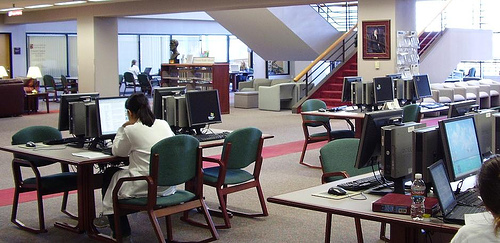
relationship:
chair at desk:
[312, 129, 419, 199] [306, 169, 430, 227]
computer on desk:
[143, 82, 186, 116] [8, 111, 273, 240]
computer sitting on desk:
[438, 117, 483, 210] [0, 127, 275, 241]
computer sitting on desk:
[183, 88, 230, 145] [0, 127, 275, 241]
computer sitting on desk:
[95, 96, 155, 156] [0, 127, 275, 241]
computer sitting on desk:
[373, 75, 400, 110] [0, 127, 275, 241]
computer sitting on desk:
[409, 75, 445, 108] [0, 127, 275, 241]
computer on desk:
[412, 74, 434, 100] [295, 105, 365, 170]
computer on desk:
[438, 115, 486, 210] [252, 83, 479, 173]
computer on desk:
[412, 74, 434, 100] [304, 90, 496, 160]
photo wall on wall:
[357, 22, 395, 63] [344, 0, 400, 80]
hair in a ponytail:
[125, 92, 155, 127] [134, 92, 153, 125]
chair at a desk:
[204, 128, 282, 239] [292, 80, 373, 134]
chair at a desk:
[10, 125, 82, 240] [290, 185, 369, 210]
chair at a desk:
[113, 136, 210, 241] [290, 185, 369, 210]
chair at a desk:
[282, 102, 350, 173] [273, 62, 485, 172]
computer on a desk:
[95, 92, 135, 157] [0, 127, 275, 241]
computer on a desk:
[59, 88, 96, 141] [2, 122, 291, 228]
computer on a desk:
[438, 115, 486, 210] [279, 180, 489, 237]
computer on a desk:
[359, 108, 400, 158] [279, 180, 489, 237]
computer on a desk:
[409, 136, 493, 241] [270, 158, 483, 241]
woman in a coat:
[98, 87, 189, 227] [97, 113, 190, 213]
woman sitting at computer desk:
[98, 87, 189, 227] [0, 126, 273, 241]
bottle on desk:
[409, 172, 426, 222] [267, 170, 464, 232]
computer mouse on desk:
[321, 177, 356, 204] [251, 163, 348, 219]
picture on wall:
[359, 18, 399, 63] [351, 3, 433, 87]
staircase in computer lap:
[306, 62, 353, 110] [12, 14, 497, 232]